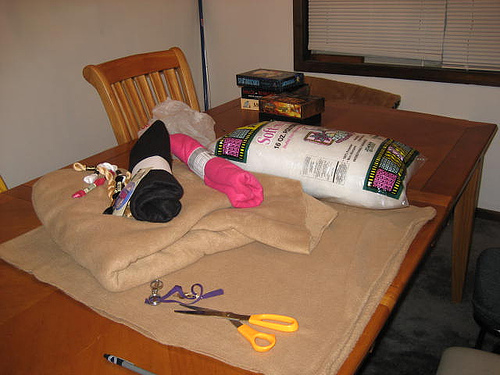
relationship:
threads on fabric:
[56, 148, 136, 230] [120, 115, 276, 212]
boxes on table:
[242, 71, 305, 135] [197, 86, 499, 215]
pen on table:
[97, 342, 137, 373] [197, 86, 499, 215]